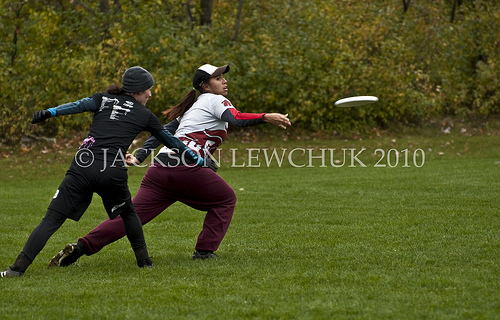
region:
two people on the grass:
[0, 37, 299, 284]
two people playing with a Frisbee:
[3, 51, 406, 287]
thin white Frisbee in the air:
[326, 84, 389, 115]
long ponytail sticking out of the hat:
[160, 61, 227, 121]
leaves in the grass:
[382, 132, 465, 160]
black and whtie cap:
[186, 56, 231, 96]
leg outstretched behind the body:
[48, 159, 182, 265]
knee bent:
[199, 183, 245, 220]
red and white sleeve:
[218, 105, 269, 130]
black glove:
[26, 103, 47, 133]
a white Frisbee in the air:
[332, 95, 378, 108]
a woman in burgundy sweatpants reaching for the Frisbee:
[48, 62, 291, 266]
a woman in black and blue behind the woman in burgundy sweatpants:
[2, 66, 222, 281]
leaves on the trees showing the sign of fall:
[2, 4, 496, 62]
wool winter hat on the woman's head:
[120, 65, 155, 92]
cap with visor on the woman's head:
[190, 60, 230, 85]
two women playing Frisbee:
[0, 60, 376, 275]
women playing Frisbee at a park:
[0, 60, 497, 317]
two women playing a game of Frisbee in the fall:
[0, 0, 495, 312]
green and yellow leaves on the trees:
[0, 1, 115, 83]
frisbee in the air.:
[334, 89, 381, 116]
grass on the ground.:
[323, 237, 394, 273]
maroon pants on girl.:
[192, 188, 238, 230]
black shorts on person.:
[52, 190, 87, 212]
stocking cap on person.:
[122, 65, 146, 90]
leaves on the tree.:
[255, 45, 292, 81]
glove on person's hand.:
[30, 104, 51, 123]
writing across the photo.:
[289, 147, 431, 165]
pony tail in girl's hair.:
[162, 86, 193, 121]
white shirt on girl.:
[187, 101, 212, 131]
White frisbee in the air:
[328, 87, 385, 111]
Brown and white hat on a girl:
[187, 62, 227, 82]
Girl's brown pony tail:
[161, 87, 197, 119]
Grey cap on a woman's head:
[117, 67, 158, 92]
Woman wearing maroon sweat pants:
[133, 161, 243, 256]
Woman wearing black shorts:
[43, 149, 144, 219]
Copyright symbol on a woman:
[73, 147, 93, 167]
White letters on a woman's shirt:
[100, 95, 135, 125]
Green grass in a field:
[278, 240, 499, 319]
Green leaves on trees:
[37, 25, 384, 95]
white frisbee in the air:
[333, 95, 380, 106]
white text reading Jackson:
[98, 146, 223, 173]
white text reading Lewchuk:
[223, 143, 367, 171]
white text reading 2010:
[369, 145, 430, 168]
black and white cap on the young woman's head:
[177, 60, 237, 82]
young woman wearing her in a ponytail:
[162, 60, 255, 142]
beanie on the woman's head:
[115, 63, 152, 95]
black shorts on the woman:
[45, 140, 134, 220]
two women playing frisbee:
[5, 52, 430, 272]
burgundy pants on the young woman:
[48, 158, 243, 259]